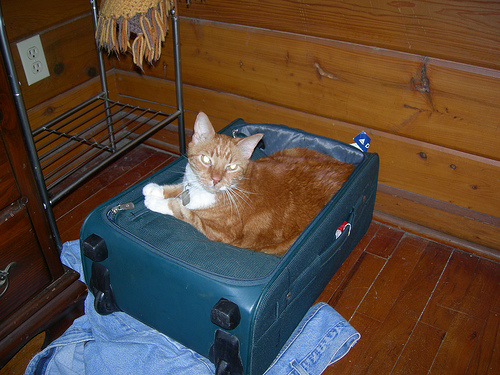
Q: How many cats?
A: One.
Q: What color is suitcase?
A: Blue.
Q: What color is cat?
A: Orange.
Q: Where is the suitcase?
A: On the floor.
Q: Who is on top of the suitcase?
A: The cat.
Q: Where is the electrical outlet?
A: On the wall.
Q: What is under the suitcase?
A: Denim.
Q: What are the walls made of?
A: Wood paneling.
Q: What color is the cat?
A: Orange.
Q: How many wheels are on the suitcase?
A: Two.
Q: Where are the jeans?
A: Under the suitcase.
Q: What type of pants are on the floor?
A: Jeans.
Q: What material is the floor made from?
A: Wood.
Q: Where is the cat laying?
A: In a suitcase.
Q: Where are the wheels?
A: Suitcase.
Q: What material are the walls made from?
A: Wood.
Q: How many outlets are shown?
A: 1.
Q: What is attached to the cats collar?
A: Tags.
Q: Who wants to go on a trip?
A: Cat.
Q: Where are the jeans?
A: Under suitcase.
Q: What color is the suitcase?
A: Blue.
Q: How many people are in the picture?
A: None.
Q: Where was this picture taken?
A: In a house.